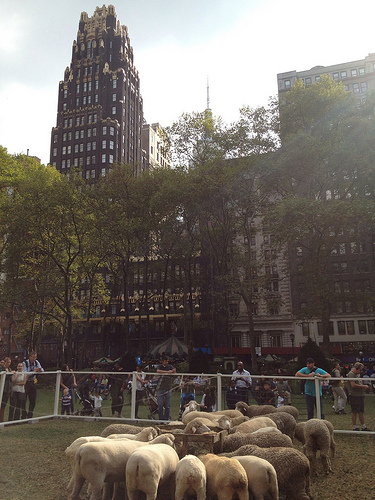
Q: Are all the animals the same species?
A: Yes, all the animals are sheep.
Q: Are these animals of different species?
A: No, all the animals are sheep.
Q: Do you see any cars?
A: No, there are no cars.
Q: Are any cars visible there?
A: No, there are no cars.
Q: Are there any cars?
A: No, there are no cars.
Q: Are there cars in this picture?
A: No, there are no cars.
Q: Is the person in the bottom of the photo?
A: Yes, the person is in the bottom of the image.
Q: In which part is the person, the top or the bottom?
A: The person is in the bottom of the image.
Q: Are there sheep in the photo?
A: Yes, there is a sheep.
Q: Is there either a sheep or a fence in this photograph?
A: Yes, there is a sheep.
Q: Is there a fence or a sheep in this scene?
A: Yes, there is a sheep.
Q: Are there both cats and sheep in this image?
A: No, there is a sheep but no cats.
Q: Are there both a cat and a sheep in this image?
A: No, there is a sheep but no cats.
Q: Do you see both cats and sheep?
A: No, there is a sheep but no cats.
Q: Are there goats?
A: No, there are no goats.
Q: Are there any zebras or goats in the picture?
A: No, there are no goats or zebras.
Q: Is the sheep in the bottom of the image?
A: Yes, the sheep is in the bottom of the image.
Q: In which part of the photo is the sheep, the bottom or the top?
A: The sheep is in the bottom of the image.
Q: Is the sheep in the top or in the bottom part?
A: The sheep is in the bottom of the image.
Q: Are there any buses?
A: No, there are no buses.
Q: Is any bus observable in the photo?
A: No, there are no buses.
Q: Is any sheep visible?
A: Yes, there is a sheep.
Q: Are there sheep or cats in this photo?
A: Yes, there is a sheep.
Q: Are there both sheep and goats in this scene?
A: No, there is a sheep but no goats.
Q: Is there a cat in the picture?
A: No, there are no cats.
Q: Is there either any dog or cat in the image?
A: No, there are no cats or dogs.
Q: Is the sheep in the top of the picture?
A: No, the sheep is in the bottom of the image.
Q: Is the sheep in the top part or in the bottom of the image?
A: The sheep is in the bottom of the image.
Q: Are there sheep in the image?
A: Yes, there is a sheep.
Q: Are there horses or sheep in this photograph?
A: Yes, there is a sheep.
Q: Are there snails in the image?
A: No, there are no snails.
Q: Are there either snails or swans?
A: No, there are no snails or swans.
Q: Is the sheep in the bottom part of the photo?
A: Yes, the sheep is in the bottom of the image.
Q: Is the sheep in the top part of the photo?
A: No, the sheep is in the bottom of the image.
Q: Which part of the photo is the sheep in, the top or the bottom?
A: The sheep is in the bottom of the image.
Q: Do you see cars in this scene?
A: No, there are no cars.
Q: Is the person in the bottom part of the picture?
A: Yes, the person is in the bottom of the image.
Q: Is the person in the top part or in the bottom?
A: The person is in the bottom of the image.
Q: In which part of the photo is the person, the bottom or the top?
A: The person is in the bottom of the image.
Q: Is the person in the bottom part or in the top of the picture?
A: The person is in the bottom of the image.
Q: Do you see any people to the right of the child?
A: Yes, there is a person to the right of the child.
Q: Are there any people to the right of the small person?
A: Yes, there is a person to the right of the child.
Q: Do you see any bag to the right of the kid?
A: No, there is a person to the right of the kid.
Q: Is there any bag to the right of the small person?
A: No, there is a person to the right of the kid.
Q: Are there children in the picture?
A: Yes, there is a child.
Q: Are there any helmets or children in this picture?
A: Yes, there is a child.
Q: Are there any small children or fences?
A: Yes, there is a small child.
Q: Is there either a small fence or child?
A: Yes, there is a small child.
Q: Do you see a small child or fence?
A: Yes, there is a small child.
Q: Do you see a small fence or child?
A: Yes, there is a small child.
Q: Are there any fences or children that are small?
A: Yes, the child is small.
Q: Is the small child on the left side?
A: Yes, the child is on the left of the image.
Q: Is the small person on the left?
A: Yes, the child is on the left of the image.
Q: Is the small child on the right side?
A: No, the child is on the left of the image.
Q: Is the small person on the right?
A: No, the child is on the left of the image.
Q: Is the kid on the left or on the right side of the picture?
A: The kid is on the left of the image.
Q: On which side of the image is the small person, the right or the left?
A: The kid is on the left of the image.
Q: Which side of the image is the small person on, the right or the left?
A: The kid is on the left of the image.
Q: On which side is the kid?
A: The kid is on the left of the image.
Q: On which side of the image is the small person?
A: The kid is on the left of the image.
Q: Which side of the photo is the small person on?
A: The kid is on the left of the image.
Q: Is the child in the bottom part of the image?
A: Yes, the child is in the bottom of the image.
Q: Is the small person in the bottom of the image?
A: Yes, the child is in the bottom of the image.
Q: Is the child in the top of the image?
A: No, the child is in the bottom of the image.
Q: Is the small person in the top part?
A: No, the child is in the bottom of the image.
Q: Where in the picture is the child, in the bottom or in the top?
A: The child is in the bottom of the image.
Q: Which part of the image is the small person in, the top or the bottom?
A: The child is in the bottom of the image.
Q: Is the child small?
A: Yes, the child is small.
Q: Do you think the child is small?
A: Yes, the child is small.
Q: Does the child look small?
A: Yes, the child is small.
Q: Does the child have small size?
A: Yes, the child is small.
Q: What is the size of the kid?
A: The kid is small.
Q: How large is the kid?
A: The kid is small.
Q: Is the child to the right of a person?
A: No, the child is to the left of a person.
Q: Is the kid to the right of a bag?
A: No, the kid is to the right of a person.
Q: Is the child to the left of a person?
A: No, the child is to the right of a person.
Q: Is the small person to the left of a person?
A: No, the child is to the right of a person.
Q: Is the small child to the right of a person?
A: Yes, the child is to the right of a person.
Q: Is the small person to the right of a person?
A: Yes, the child is to the right of a person.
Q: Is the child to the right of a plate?
A: No, the child is to the right of a person.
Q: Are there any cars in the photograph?
A: No, there are no cars.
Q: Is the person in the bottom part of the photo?
A: Yes, the person is in the bottom of the image.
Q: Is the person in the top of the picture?
A: No, the person is in the bottom of the image.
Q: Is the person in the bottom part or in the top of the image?
A: The person is in the bottom of the image.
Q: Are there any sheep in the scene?
A: Yes, there is a sheep.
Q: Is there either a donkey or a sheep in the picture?
A: Yes, there is a sheep.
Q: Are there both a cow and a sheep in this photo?
A: No, there is a sheep but no cows.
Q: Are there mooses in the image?
A: No, there are no mooses.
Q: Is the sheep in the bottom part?
A: Yes, the sheep is in the bottom of the image.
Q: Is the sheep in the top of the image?
A: No, the sheep is in the bottom of the image.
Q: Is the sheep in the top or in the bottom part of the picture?
A: The sheep is in the bottom of the image.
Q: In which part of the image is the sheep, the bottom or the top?
A: The sheep is in the bottom of the image.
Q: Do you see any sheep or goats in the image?
A: Yes, there is a sheep.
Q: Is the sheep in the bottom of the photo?
A: Yes, the sheep is in the bottom of the image.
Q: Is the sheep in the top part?
A: No, the sheep is in the bottom of the image.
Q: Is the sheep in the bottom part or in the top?
A: The sheep is in the bottom of the image.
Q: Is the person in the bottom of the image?
A: Yes, the person is in the bottom of the image.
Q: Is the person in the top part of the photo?
A: No, the person is in the bottom of the image.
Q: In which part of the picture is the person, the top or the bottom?
A: The person is in the bottom of the image.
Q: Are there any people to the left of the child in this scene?
A: Yes, there is a person to the left of the child.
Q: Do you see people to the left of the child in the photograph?
A: Yes, there is a person to the left of the child.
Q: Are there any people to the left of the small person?
A: Yes, there is a person to the left of the child.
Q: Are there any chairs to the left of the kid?
A: No, there is a person to the left of the kid.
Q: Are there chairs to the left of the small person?
A: No, there is a person to the left of the kid.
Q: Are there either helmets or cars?
A: No, there are no cars or helmets.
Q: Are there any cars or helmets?
A: No, there are no cars or helmets.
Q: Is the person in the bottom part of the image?
A: Yes, the person is in the bottom of the image.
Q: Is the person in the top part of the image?
A: No, the person is in the bottom of the image.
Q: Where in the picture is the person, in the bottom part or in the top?
A: The person is in the bottom of the image.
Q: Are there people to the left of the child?
A: Yes, there is a person to the left of the child.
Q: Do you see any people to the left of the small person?
A: Yes, there is a person to the left of the child.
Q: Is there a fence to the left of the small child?
A: No, there is a person to the left of the kid.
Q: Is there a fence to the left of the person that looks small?
A: No, there is a person to the left of the kid.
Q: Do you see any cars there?
A: No, there are no cars.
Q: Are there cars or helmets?
A: No, there are no cars or helmets.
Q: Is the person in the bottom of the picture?
A: Yes, the person is in the bottom of the image.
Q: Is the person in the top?
A: No, the person is in the bottom of the image.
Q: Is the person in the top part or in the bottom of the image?
A: The person is in the bottom of the image.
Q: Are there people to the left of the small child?
A: Yes, there is a person to the left of the child.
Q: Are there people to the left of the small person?
A: Yes, there is a person to the left of the child.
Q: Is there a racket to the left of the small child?
A: No, there is a person to the left of the child.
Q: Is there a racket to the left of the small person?
A: No, there is a person to the left of the child.